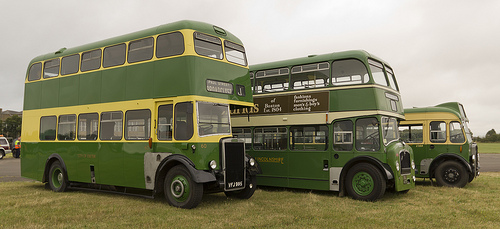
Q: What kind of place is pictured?
A: It is a field.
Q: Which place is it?
A: It is a field.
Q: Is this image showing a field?
A: Yes, it is showing a field.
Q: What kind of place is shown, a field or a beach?
A: It is a field.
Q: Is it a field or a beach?
A: It is a field.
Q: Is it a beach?
A: No, it is a field.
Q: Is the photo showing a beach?
A: No, the picture is showing a field.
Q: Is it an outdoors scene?
A: Yes, it is outdoors.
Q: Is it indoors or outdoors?
A: It is outdoors.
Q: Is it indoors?
A: No, it is outdoors.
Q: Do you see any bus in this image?
A: Yes, there is a bus.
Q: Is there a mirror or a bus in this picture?
A: Yes, there is a bus.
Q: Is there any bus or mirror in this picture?
A: Yes, there is a bus.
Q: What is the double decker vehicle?
A: The vehicle is a bus.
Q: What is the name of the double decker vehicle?
A: The vehicle is a bus.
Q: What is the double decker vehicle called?
A: The vehicle is a bus.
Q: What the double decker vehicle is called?
A: The vehicle is a bus.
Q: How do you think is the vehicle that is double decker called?
A: The vehicle is a bus.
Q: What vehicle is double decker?
A: The vehicle is a bus.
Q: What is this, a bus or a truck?
A: This is a bus.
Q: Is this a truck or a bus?
A: This is a bus.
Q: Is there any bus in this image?
A: Yes, there is a bus.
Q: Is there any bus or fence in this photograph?
A: Yes, there is a bus.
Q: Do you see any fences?
A: No, there are no fences.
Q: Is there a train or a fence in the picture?
A: No, there are no fences or trains.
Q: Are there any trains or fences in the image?
A: No, there are no fences or trains.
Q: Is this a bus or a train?
A: This is a bus.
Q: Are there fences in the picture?
A: No, there are no fences.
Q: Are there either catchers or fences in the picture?
A: No, there are no fences or catchers.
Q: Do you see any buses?
A: Yes, there is a bus.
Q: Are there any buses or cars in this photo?
A: Yes, there is a bus.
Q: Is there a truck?
A: No, there are no trucks.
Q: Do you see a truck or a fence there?
A: No, there are no trucks or fences.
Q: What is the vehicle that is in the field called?
A: The vehicle is a bus.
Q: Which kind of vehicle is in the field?
A: The vehicle is a bus.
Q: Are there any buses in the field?
A: Yes, there is a bus in the field.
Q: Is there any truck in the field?
A: No, there is a bus in the field.